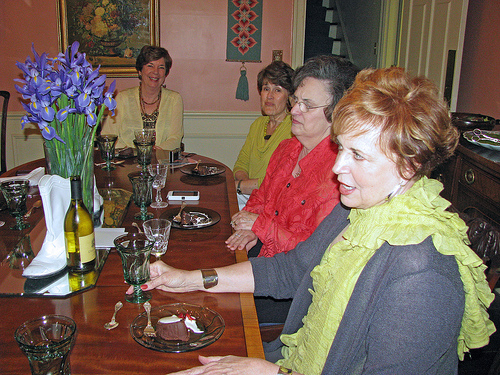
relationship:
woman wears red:
[276, 57, 346, 221] [248, 135, 341, 258]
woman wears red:
[224, 57, 364, 259] [248, 135, 341, 258]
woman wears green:
[229, 55, 312, 200] [229, 116, 295, 188]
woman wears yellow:
[97, 39, 197, 166] [88, 90, 204, 166]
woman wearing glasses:
[224, 57, 364, 259] [283, 92, 321, 115]